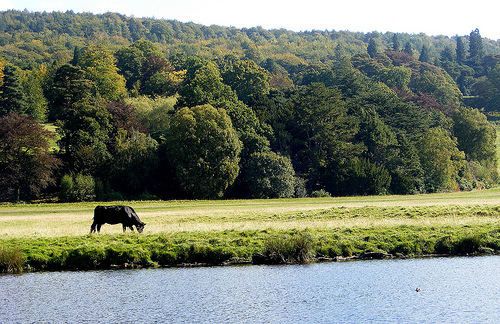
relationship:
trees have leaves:
[332, 85, 447, 185] [434, 140, 456, 160]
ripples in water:
[144, 298, 195, 305] [320, 257, 485, 322]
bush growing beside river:
[270, 231, 317, 262] [201, 240, 494, 315]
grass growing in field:
[0, 209, 78, 230] [155, 200, 493, 224]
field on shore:
[155, 200, 493, 224] [1, 234, 499, 261]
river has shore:
[0, 243, 499, 322] [1, 234, 499, 261]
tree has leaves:
[166, 108, 243, 195] [114, 106, 131, 122]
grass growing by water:
[0, 209, 78, 230] [0, 256, 499, 322]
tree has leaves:
[161, 104, 236, 198] [93, 61, 290, 153]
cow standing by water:
[82, 197, 150, 237] [0, 256, 499, 322]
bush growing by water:
[270, 231, 321, 266] [33, 276, 488, 321]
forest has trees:
[3, 0, 484, 182] [2, 37, 156, 197]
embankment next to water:
[2, 234, 498, 256] [6, 248, 476, 323]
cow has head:
[82, 197, 150, 237] [133, 220, 147, 232]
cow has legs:
[82, 197, 150, 237] [127, 224, 134, 233]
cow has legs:
[82, 197, 150, 237] [120, 222, 125, 232]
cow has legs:
[82, 197, 150, 237] [97, 221, 101, 233]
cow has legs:
[82, 197, 150, 237] [91, 223, 93, 233]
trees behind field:
[20, 7, 488, 198] [2, 186, 493, 278]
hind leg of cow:
[89, 218, 102, 233] [82, 197, 150, 237]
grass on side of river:
[0, 209, 78, 230] [0, 243, 499, 322]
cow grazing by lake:
[82, 197, 150, 237] [6, 259, 498, 322]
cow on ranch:
[82, 197, 150, 237] [3, 184, 496, 272]